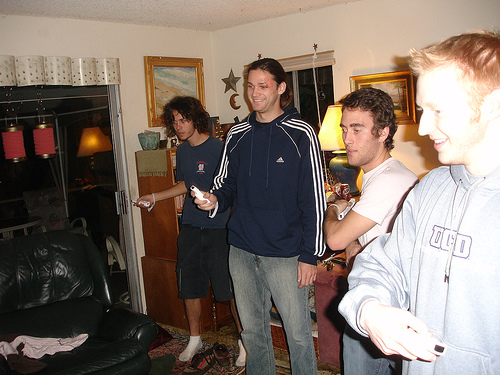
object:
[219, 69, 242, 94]
star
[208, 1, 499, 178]
wall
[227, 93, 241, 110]
moon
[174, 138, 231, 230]
shirt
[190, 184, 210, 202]
controller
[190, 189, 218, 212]
hand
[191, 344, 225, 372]
shoe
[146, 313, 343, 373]
floor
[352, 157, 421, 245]
t-shirt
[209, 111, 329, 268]
hoodie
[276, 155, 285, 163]
logo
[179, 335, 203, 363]
sock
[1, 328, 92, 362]
cloth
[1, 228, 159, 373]
chair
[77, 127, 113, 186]
lamp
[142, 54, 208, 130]
frame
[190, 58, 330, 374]
man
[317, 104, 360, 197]
light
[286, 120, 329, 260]
stripe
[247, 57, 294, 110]
hair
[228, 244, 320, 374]
jeans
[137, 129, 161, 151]
bowl